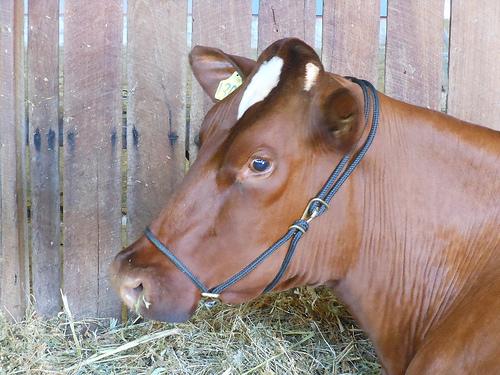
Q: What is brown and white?
A: The cow.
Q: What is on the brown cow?
A: Black halter.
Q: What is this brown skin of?
A: A cow.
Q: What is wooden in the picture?
A: Fence.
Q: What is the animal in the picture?
A: Cow.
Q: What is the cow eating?
A: Hay.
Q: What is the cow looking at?
A: Camera.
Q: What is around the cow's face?
A: Muzzle.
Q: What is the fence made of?
A: Wood.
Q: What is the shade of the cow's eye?
A: Black.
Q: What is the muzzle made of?
A: Rope.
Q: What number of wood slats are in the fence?
A: 10.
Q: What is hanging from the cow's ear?
A: Tag.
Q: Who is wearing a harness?
A: A cow is.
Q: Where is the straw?
A: On the ground.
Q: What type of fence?
A: Wooden fence.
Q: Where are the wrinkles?
A: On the neck.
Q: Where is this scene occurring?
A: In a barn stall.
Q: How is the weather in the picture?
A: Warm and dry.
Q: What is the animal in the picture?
A: Cow.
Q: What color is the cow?
A: Brown.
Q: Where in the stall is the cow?
A: Against the wall.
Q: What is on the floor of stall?
A: Straw.